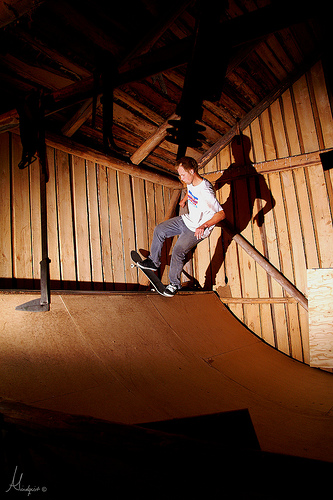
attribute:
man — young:
[130, 138, 264, 305]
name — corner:
[7, 463, 56, 498]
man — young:
[131, 154, 227, 297]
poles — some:
[219, 227, 312, 306]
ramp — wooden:
[1, 289, 332, 492]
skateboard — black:
[129, 248, 167, 295]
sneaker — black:
[136, 257, 155, 266]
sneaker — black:
[164, 281, 179, 294]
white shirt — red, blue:
[181, 176, 224, 239]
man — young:
[134, 153, 223, 289]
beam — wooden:
[9, 13, 165, 129]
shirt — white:
[178, 179, 224, 241]